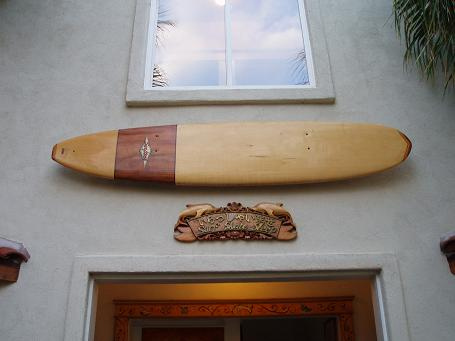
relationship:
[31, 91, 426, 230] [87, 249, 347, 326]
wood above doorway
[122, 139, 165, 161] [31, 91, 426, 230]
decal on board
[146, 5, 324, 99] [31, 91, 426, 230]
window above board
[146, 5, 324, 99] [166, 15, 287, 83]
window has reflection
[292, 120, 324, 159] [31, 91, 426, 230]
hole in board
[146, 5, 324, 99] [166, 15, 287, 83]
window with reflection